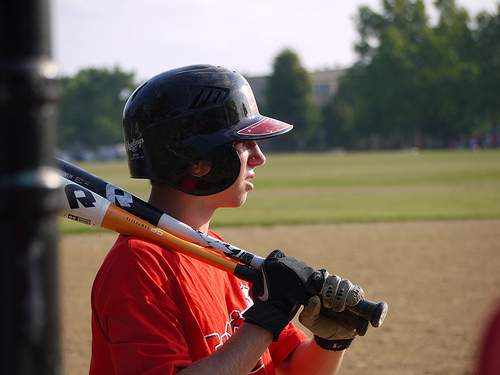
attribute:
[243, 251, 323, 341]
glove — black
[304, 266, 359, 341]
glove — grey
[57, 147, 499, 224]
field — mowed, neat, grassy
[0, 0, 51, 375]
pole — black, tall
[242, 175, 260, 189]
mouth — open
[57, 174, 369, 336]
bat — orange, black, white, wood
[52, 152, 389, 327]
bat — black, white, wood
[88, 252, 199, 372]
top — red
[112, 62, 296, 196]
helmet — blue, red, navy, black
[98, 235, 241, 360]
jersey — orange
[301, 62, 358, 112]
tan-colored building — tan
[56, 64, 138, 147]
tree — green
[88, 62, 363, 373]
boy — young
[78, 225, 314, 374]
shirt — red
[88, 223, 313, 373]
uniform top — orange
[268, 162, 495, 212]
grass — green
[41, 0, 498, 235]
plants — green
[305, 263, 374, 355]
glove — grey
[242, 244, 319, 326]
glove — black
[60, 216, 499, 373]
ground — dirt, brown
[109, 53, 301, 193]
helmet — black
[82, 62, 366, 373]
player — baseball player